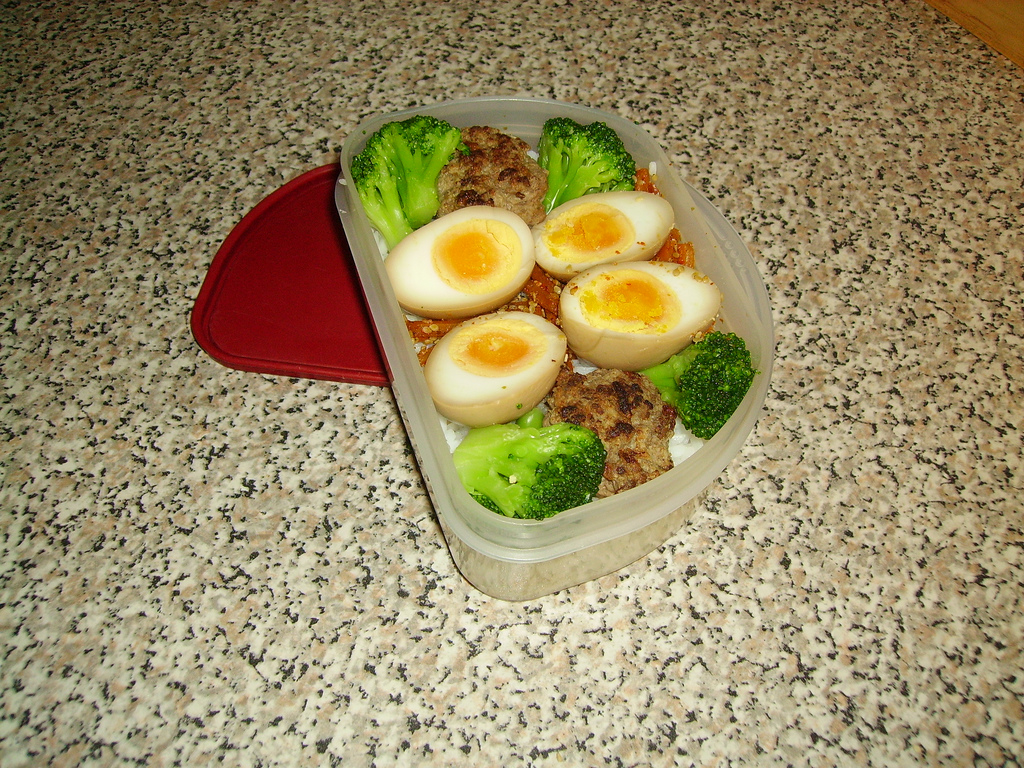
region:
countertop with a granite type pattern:
[2, 0, 1018, 766]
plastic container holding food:
[337, 91, 774, 595]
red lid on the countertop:
[193, 148, 394, 395]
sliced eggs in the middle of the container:
[374, 186, 722, 425]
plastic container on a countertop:
[1, 1, 1017, 766]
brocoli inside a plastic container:
[326, 95, 772, 608]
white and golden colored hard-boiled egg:
[378, 199, 534, 323]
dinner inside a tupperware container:
[327, 85, 781, 602]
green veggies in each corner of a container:
[333, 88, 776, 600]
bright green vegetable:
[449, 418, 605, 521]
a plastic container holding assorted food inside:
[325, 92, 787, 611]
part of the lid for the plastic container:
[189, 152, 386, 399]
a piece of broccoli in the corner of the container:
[360, 116, 458, 233]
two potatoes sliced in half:
[384, 189, 732, 417]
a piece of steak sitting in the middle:
[543, 361, 673, 497]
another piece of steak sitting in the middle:
[435, 123, 546, 222]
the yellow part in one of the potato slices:
[423, 218, 518, 292]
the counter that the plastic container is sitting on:
[10, 7, 1022, 750]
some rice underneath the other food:
[664, 424, 700, 463]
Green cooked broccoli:
[448, 413, 608, 531]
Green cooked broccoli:
[531, 110, 642, 225]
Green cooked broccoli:
[341, 105, 465, 260]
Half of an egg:
[423, 309, 567, 414]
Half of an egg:
[375, 199, 540, 321]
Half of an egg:
[553, 258, 728, 370]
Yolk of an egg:
[446, 316, 548, 378]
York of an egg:
[575, 260, 684, 336]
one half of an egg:
[383, 192, 540, 329]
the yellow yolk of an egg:
[438, 227, 505, 273]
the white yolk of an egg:
[386, 236, 453, 300]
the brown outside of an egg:
[494, 394, 543, 429]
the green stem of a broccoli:
[435, 426, 537, 490]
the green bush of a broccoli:
[509, 432, 599, 493]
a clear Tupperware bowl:
[479, 516, 601, 603]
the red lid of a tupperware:
[204, 192, 323, 358]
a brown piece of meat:
[573, 367, 666, 469]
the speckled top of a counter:
[830, 429, 961, 630]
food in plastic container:
[335, 102, 772, 599]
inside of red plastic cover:
[190, 160, 383, 385]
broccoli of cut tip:
[374, 117, 461, 225]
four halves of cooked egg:
[386, 186, 720, 428]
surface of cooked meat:
[549, 367, 674, 497]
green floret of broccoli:
[524, 441, 607, 515]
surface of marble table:
[4, 5, 1020, 764]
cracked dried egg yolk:
[434, 219, 518, 290]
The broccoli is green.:
[473, 415, 626, 511]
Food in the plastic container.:
[443, 167, 704, 427]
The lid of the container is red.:
[187, 154, 369, 370]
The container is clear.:
[319, 132, 773, 584]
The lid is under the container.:
[189, 170, 475, 458]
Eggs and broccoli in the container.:
[382, 148, 652, 300]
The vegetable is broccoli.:
[354, 117, 501, 220]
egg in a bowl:
[447, 191, 514, 291]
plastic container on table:
[308, 78, 805, 604]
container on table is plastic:
[317, 93, 783, 613]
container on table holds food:
[314, 74, 790, 615]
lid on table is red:
[187, 144, 653, 421]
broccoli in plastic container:
[440, 415, 619, 527]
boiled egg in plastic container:
[373, 188, 741, 430]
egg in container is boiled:
[358, 182, 725, 410]